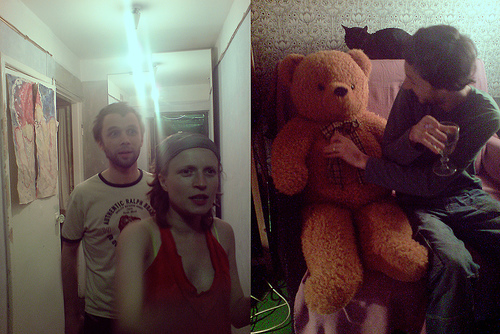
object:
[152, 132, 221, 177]
bandana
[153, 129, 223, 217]
head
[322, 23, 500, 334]
man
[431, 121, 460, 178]
glass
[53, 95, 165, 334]
man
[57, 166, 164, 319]
shirt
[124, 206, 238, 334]
shirt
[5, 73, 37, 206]
painting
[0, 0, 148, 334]
wall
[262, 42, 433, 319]
teddy bear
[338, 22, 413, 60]
cat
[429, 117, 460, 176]
cup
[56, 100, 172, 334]
man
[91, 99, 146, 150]
hair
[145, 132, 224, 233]
hair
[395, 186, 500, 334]
pants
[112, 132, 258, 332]
lady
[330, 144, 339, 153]
ring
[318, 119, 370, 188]
bowtie